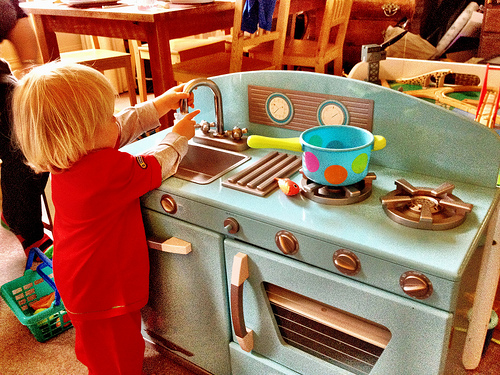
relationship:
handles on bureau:
[381, 0, 404, 19] [303, 0, 421, 63]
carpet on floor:
[11, 335, 65, 369] [5, 324, 56, 359]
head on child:
[7, 59, 132, 171] [11, 62, 197, 372]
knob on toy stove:
[156, 195, 176, 214] [223, 90, 499, 374]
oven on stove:
[221, 244, 446, 371] [224, 164, 499, 375]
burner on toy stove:
[380, 179, 474, 231] [116, 69, 499, 372]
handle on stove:
[225, 249, 258, 355] [98, 70, 496, 373]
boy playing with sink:
[11, 62, 196, 373] [110, 62, 490, 373]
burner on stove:
[375, 168, 477, 235] [211, 105, 484, 372]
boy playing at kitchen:
[11, 62, 196, 373] [106, 60, 498, 373]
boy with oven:
[11, 62, 196, 373] [223, 161, 488, 373]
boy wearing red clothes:
[11, 60, 196, 373] [40, 149, 171, 374]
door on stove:
[221, 235, 451, 375] [224, 55, 499, 375]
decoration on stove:
[244, 84, 374, 141] [98, 70, 496, 373]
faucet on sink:
[175, 69, 232, 144] [132, 126, 254, 206]